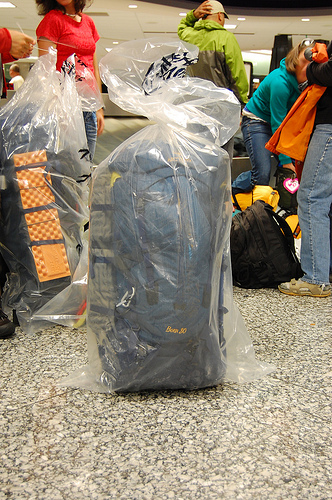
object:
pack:
[0, 102, 88, 320]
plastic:
[0, 46, 106, 338]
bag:
[88, 125, 229, 396]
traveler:
[231, 40, 312, 198]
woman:
[35, 0, 104, 162]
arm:
[305, 64, 332, 87]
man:
[178, 0, 249, 118]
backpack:
[229, 194, 302, 289]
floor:
[0, 284, 331, 500]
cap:
[198, 0, 232, 20]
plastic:
[51, 35, 279, 396]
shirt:
[35, 9, 102, 99]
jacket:
[263, 44, 329, 164]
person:
[277, 31, 331, 298]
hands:
[7, 29, 33, 53]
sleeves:
[0, 26, 11, 56]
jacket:
[165, 10, 257, 109]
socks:
[280, 277, 329, 290]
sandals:
[277, 275, 330, 297]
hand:
[194, 1, 212, 19]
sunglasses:
[299, 39, 316, 46]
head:
[196, 0, 225, 28]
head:
[291, 38, 319, 85]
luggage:
[228, 164, 302, 265]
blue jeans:
[80, 108, 97, 160]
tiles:
[1, 337, 331, 500]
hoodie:
[245, 56, 305, 166]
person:
[7, 62, 24, 94]